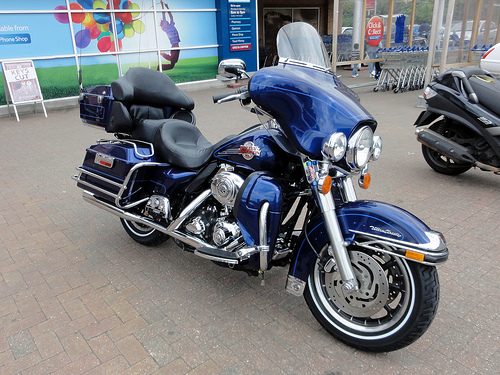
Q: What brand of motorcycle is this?
A: It is a Harley.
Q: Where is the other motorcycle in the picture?
A: It is to the right?.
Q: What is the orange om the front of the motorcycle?
A: Reflectors.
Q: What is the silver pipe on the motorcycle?
A: It is the muffler.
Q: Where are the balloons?
A: On an advertisement in the store window.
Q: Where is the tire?
A: On the motorcycle.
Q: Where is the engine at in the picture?
A: On the motorcycle.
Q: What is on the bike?
A: Tires.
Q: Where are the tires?
A: On the bike.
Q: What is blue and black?
A: Bike.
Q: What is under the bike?
A: Cement.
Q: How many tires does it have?
A: Two.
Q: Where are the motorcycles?
A: On the sidewalk.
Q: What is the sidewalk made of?
A: Bricks.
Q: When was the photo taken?
A: Daytime.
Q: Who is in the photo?
A: Nobody.